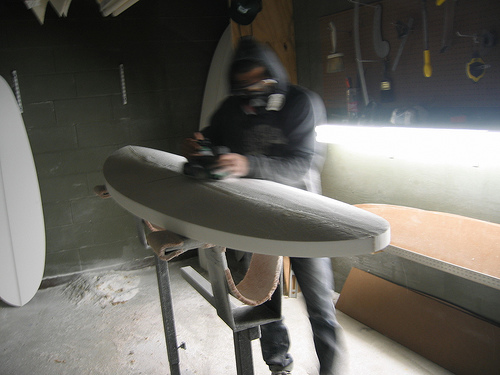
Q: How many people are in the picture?
A: One.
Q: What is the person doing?
A: Sanding.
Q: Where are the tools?
A: On the wall.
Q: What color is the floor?
A: Gray.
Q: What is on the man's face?
A: A breathing mask.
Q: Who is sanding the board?
A: The man.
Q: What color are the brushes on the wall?
A: White and Black.